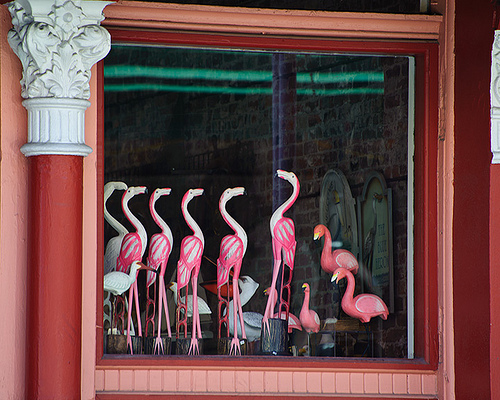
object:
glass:
[100, 43, 419, 361]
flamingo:
[145, 187, 173, 355]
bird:
[261, 169, 300, 338]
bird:
[217, 186, 248, 357]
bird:
[299, 283, 320, 356]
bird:
[115, 186, 149, 355]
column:
[7, 0, 111, 400]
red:
[271, 55, 295, 209]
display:
[101, 169, 390, 363]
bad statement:
[0, 0, 500, 400]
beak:
[314, 233, 320, 241]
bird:
[331, 267, 389, 358]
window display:
[99, 41, 416, 358]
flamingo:
[177, 188, 205, 356]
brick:
[94, 367, 438, 396]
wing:
[273, 218, 295, 251]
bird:
[314, 224, 360, 320]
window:
[100, 21, 448, 369]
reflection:
[101, 63, 388, 97]